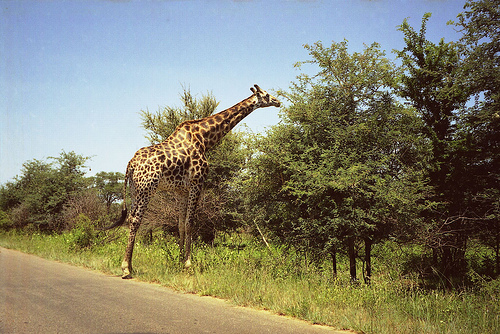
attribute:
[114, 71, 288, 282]
giraffe — tall, brown, tan